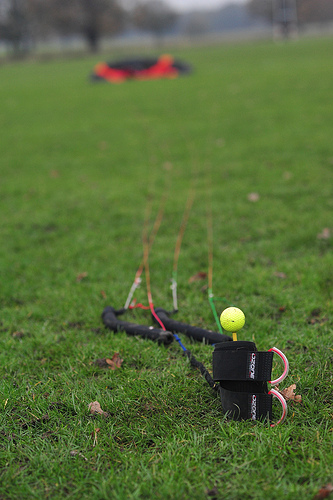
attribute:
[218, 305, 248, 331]
green ball — small, round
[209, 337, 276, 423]
cloth harness — large, black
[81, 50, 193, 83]
large kite — black and orange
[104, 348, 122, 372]
dead leaf — small, brown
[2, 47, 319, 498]
grassy field — large, open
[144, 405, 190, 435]
short tuft — green grass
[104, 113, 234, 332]
lines — long, colored, thin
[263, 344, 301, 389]
handles — short, round, red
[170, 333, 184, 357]
line — thin, blue, cloth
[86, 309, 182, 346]
strap — long, large, black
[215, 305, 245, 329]
golf ball — yellow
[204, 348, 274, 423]
parachute grips — black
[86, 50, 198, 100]
parachute — black, red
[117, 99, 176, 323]
rope — red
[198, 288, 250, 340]
rope — green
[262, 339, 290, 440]
hand grips — red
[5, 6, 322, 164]
focus — out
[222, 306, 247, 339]
golf ball — yellow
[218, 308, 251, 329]
golf ball — yellow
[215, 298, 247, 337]
golf ball — yellow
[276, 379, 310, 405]
leaf — dry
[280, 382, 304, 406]
leaf — dry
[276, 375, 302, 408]
leaf — dry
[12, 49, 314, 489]
grass — green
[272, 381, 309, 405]
leaf — dry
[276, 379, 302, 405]
leaf — dry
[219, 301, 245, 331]
ball — green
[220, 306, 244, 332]
ball — green 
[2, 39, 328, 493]
grass — green 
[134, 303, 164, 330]
string — pink 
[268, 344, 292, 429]
grip — red and white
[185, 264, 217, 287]
leaf — brown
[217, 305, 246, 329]
golfball — small, white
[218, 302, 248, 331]
ball — yellow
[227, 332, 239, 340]
stick — orange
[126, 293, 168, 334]
object — red, black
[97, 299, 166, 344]
handle — black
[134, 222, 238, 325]
strings — pink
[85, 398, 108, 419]
leaf — brown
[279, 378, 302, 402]
leaf — brown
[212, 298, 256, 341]
golf ball — yellow